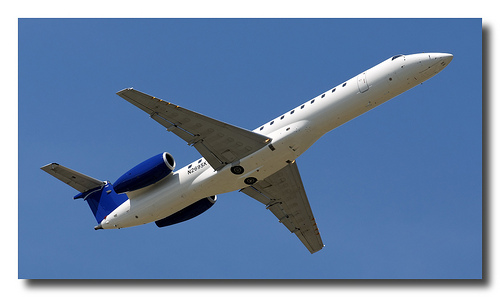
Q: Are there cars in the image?
A: No, there are no cars.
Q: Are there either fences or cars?
A: No, there are no cars or fences.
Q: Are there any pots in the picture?
A: No, there are no pots.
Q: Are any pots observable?
A: No, there are no pots.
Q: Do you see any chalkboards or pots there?
A: No, there are no pots or chalkboards.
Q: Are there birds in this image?
A: No, there are no birds.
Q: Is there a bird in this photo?
A: No, there are no birds.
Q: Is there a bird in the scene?
A: No, there are no birds.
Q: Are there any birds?
A: No, there are no birds.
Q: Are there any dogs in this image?
A: No, there are no dogs.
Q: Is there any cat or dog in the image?
A: No, there are no dogs or cats.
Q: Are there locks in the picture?
A: No, there are no locks.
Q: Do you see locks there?
A: No, there are no locks.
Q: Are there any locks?
A: No, there are no locks.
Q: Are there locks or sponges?
A: No, there are no locks or sponges.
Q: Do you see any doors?
A: Yes, there is a door.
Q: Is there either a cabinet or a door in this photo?
A: Yes, there is a door.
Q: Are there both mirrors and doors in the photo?
A: No, there is a door but no mirrors.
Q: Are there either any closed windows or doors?
A: Yes, there is a closed door.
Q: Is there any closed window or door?
A: Yes, there is a closed door.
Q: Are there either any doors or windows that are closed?
A: Yes, the door is closed.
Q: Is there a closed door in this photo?
A: Yes, there is a closed door.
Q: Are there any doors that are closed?
A: Yes, there is a door that is closed.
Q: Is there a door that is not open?
A: Yes, there is an closed door.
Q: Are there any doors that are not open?
A: Yes, there is an closed door.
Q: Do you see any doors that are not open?
A: Yes, there is an closed door.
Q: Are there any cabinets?
A: No, there are no cabinets.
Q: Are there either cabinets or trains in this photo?
A: No, there are no cabinets or trains.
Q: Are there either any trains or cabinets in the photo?
A: No, there are no cabinets or trains.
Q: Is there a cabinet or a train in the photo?
A: No, there are no cabinets or trains.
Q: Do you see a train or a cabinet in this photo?
A: No, there are no cabinets or trains.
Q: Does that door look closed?
A: Yes, the door is closed.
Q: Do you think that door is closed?
A: Yes, the door is closed.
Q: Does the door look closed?
A: Yes, the door is closed.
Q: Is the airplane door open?
A: No, the door is closed.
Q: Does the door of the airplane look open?
A: No, the door is closed.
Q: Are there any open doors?
A: No, there is a door but it is closed.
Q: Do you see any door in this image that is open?
A: No, there is a door but it is closed.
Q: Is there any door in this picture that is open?
A: No, there is a door but it is closed.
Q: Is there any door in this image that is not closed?
A: No, there is a door but it is closed.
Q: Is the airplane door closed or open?
A: The door is closed.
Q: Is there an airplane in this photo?
A: Yes, there is an airplane.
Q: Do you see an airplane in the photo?
A: Yes, there is an airplane.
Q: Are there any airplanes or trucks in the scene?
A: Yes, there is an airplane.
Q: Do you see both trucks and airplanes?
A: No, there is an airplane but no trucks.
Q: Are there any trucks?
A: No, there are no trucks.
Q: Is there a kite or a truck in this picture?
A: No, there are no trucks or kites.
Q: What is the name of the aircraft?
A: The aircraft is an airplane.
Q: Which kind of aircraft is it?
A: The aircraft is an airplane.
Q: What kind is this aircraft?
A: This is an airplane.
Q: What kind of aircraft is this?
A: This is an airplane.